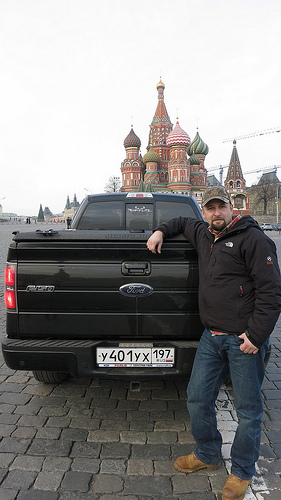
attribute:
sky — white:
[0, 2, 279, 217]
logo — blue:
[119, 283, 152, 298]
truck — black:
[1, 193, 270, 385]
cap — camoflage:
[196, 182, 234, 208]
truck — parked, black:
[16, 199, 204, 374]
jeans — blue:
[185, 328, 270, 478]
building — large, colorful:
[120, 74, 251, 216]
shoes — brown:
[207, 470, 249, 497]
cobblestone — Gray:
[56, 469, 220, 491]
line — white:
[213, 383, 272, 498]